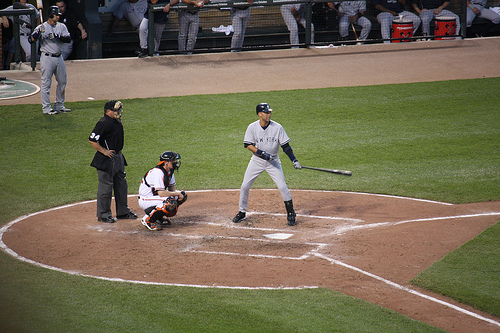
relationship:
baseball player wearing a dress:
[231, 102, 301, 225] [239, 119, 298, 212]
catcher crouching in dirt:
[138, 150, 188, 231] [26, 190, 448, 285]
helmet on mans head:
[46, 5, 64, 15] [43, 1, 65, 21]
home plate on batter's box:
[259, 229, 297, 246] [206, 204, 369, 248]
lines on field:
[306, 213, 366, 305] [6, 93, 497, 327]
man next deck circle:
[26, 6, 72, 114] [0, 73, 42, 103]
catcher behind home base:
[132, 147, 194, 239] [258, 227, 296, 249]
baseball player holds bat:
[231, 102, 301, 225] [288, 147, 365, 186]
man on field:
[26, 6, 72, 114] [16, 65, 498, 120]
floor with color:
[0, 37, 500, 333] [392, 192, 456, 208]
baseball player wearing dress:
[231, 102, 301, 225] [233, 119, 304, 210]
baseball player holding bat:
[231, 102, 301, 225] [291, 164, 351, 179]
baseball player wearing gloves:
[231, 102, 301, 225] [256, 148, 277, 160]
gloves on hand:
[256, 148, 277, 160] [261, 149, 275, 163]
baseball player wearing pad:
[231, 102, 301, 225] [158, 197, 180, 217]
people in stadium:
[0, 0, 500, 60] [1, 2, 498, 330]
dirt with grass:
[23, 177, 410, 298] [0, 79, 497, 329]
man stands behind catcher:
[87, 100, 139, 223] [134, 147, 189, 234]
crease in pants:
[244, 154, 276, 167] [233, 150, 293, 212]